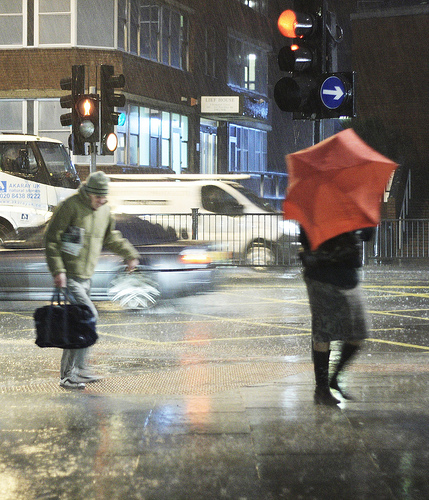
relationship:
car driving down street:
[133, 224, 212, 297] [161, 325, 258, 388]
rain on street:
[112, 346, 161, 378] [161, 325, 258, 388]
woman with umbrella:
[277, 134, 393, 413] [277, 124, 402, 254]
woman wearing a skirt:
[277, 134, 393, 413] [307, 291, 369, 341]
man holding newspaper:
[37, 170, 145, 395] [56, 227, 88, 259]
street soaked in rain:
[161, 325, 258, 388] [112, 346, 161, 378]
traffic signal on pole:
[268, 8, 318, 118] [330, 12, 342, 74]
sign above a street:
[317, 63, 349, 116] [161, 325, 258, 388]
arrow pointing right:
[326, 87, 341, 99] [332, 86, 344, 100]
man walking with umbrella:
[37, 170, 145, 395] [277, 124, 402, 254]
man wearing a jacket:
[37, 170, 145, 395] [50, 214, 103, 278]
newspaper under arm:
[56, 227, 88, 259] [43, 224, 64, 262]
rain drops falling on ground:
[401, 263, 417, 315] [147, 347, 253, 402]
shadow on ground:
[130, 279, 196, 307] [147, 347, 253, 402]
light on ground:
[165, 273, 245, 304] [147, 347, 253, 402]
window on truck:
[33, 140, 69, 188] [0, 136, 86, 231]